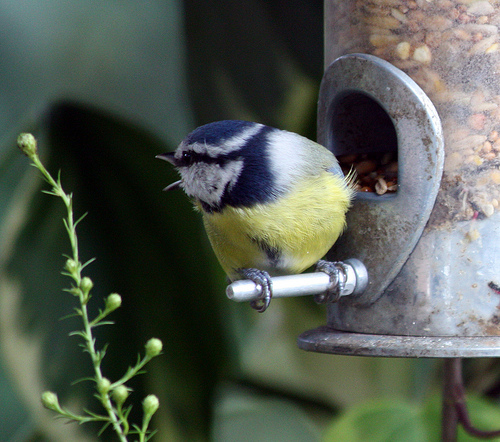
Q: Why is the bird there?
A: Food.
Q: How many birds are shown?
A: One.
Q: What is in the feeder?
A: Seed.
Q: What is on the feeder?
A: Bird.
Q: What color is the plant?
A: Green.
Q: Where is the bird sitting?
A: Stand.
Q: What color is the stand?
A: Silver.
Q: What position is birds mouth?
A: Open.